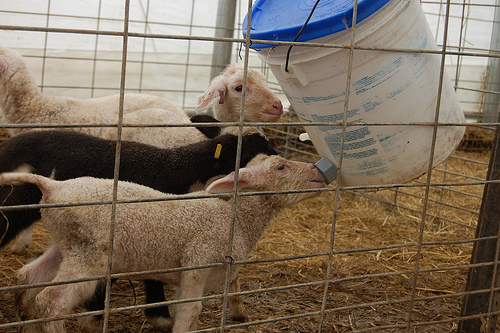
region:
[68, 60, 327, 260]
the sheep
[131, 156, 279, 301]
the sheep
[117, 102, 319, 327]
the sheep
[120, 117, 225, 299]
the sheep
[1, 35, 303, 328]
a group of lambs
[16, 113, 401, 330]
small white lamb taking a drink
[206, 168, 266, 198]
long, pointed ear pushed back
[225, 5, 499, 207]
large white container with a blue lid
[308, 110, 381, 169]
blue writing on the side of the container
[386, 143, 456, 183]
dirt smudges on the container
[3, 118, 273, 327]
dark brown lamb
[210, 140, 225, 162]
yellow tag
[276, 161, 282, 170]
small black eye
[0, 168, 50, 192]
fluffy white tail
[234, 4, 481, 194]
tilted white plastic bucket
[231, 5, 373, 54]
blue lid on bucket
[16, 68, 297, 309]
three lambs facing right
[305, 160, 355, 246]
metal bars on pen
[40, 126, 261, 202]
black sheep between white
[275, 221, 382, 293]
hay on pen floor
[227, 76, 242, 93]
eye on white sheep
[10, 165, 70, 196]
tail on black sheep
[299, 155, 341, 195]
lamb drinking from bucket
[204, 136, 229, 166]
yellow tag on lamb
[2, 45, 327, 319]
Baby sheep.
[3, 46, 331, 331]
The sheep are black and white.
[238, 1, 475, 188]
The bucket is hanging.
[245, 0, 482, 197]
The bucket is white.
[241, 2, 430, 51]
The bucket top is blue.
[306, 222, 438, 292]
The ground is covered in hay.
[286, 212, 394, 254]
The hay is yellow.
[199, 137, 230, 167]
The sheep has an ear tag.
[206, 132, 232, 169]
The ear tag is yellow.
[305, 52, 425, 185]
Writing is on the bucket.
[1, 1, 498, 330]
cage with kids in it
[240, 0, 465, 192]
large container feeding the kids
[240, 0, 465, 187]
large, white container with blue top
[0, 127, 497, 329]
ground covered in brown hay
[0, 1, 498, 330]
metal bars for the cage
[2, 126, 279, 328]
black kid in the middle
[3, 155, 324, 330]
white kid drinking from the container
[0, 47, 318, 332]
group of kids in a cage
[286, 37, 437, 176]
small blue writing on container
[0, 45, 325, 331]
kids in a cage preparing for feeding